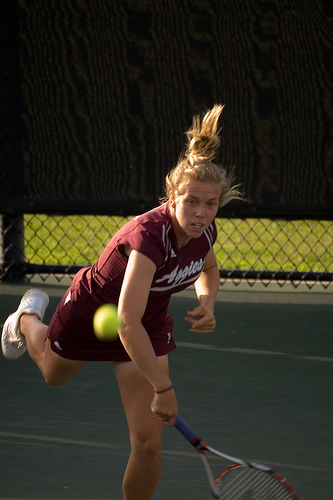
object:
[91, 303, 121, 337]
ball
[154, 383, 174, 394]
hair tie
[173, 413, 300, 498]
racket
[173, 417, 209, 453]
handle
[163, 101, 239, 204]
hair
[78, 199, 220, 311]
shirt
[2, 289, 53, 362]
shoe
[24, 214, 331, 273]
grass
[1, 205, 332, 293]
fence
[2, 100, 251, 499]
woman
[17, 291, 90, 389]
leg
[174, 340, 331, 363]
line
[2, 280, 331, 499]
tennis court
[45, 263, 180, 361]
skirt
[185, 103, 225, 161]
pony tail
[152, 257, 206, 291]
logo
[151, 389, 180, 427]
hand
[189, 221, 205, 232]
mouth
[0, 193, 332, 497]
area